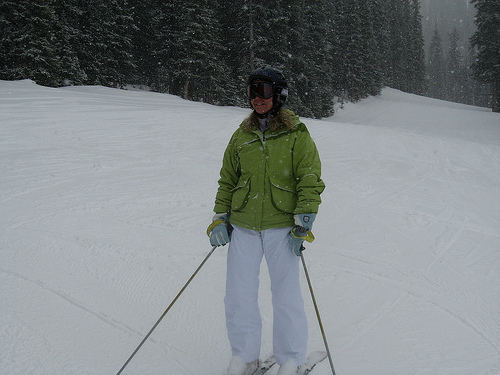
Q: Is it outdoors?
A: Yes, it is outdoors.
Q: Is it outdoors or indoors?
A: It is outdoors.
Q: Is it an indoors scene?
A: No, it is outdoors.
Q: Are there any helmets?
A: Yes, there is a helmet.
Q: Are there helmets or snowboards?
A: Yes, there is a helmet.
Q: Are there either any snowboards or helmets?
A: Yes, there is a helmet.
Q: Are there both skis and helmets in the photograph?
A: Yes, there are both a helmet and skis.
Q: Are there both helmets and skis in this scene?
A: Yes, there are both a helmet and skis.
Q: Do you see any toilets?
A: No, there are no toilets.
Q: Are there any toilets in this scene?
A: No, there are no toilets.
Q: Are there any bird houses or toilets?
A: No, there are no toilets or bird houses.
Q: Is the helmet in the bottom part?
A: No, the helmet is in the top of the image.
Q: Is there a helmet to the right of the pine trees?
A: Yes, there is a helmet to the right of the pine trees.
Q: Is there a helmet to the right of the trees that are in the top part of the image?
A: Yes, there is a helmet to the right of the pine trees.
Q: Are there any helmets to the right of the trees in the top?
A: Yes, there is a helmet to the right of the pine trees.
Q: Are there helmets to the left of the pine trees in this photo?
A: No, the helmet is to the right of the pine trees.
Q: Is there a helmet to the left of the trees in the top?
A: No, the helmet is to the right of the pine trees.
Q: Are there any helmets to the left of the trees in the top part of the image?
A: No, the helmet is to the right of the pine trees.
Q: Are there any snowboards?
A: No, there are no snowboards.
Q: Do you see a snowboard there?
A: No, there are no snowboards.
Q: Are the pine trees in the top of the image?
A: Yes, the pine trees are in the top of the image.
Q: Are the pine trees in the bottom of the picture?
A: No, the pine trees are in the top of the image.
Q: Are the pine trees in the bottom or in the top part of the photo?
A: The pine trees are in the top of the image.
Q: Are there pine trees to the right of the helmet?
A: No, the pine trees are to the left of the helmet.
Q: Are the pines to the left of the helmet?
A: Yes, the pines are to the left of the helmet.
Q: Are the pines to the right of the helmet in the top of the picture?
A: No, the pines are to the left of the helmet.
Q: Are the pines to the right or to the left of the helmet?
A: The pines are to the left of the helmet.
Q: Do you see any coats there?
A: Yes, there is a coat.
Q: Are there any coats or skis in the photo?
A: Yes, there is a coat.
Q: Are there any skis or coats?
A: Yes, there is a coat.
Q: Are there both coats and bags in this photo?
A: No, there is a coat but no bags.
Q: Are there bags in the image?
A: No, there are no bags.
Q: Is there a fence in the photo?
A: No, there are no fences.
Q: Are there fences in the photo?
A: No, there are no fences.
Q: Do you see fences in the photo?
A: No, there are no fences.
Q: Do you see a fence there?
A: No, there are no fences.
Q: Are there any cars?
A: No, there are no cars.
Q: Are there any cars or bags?
A: No, there are no cars or bags.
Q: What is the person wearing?
A: The person is wearing trousers.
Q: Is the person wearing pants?
A: Yes, the person is wearing pants.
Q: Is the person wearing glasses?
A: No, the person is wearing pants.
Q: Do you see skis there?
A: Yes, there are skis.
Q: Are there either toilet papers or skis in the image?
A: Yes, there are skis.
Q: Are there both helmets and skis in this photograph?
A: Yes, there are both skis and a helmet.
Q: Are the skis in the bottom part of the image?
A: Yes, the skis are in the bottom of the image.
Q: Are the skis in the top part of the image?
A: No, the skis are in the bottom of the image.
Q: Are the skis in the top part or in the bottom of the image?
A: The skis are in the bottom of the image.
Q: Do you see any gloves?
A: Yes, there are gloves.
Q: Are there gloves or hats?
A: Yes, there are gloves.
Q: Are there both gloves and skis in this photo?
A: Yes, there are both gloves and a ski.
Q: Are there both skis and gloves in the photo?
A: Yes, there are both gloves and a ski.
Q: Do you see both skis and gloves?
A: Yes, there are both gloves and a ski.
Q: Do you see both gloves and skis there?
A: Yes, there are both gloves and a ski.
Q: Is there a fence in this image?
A: No, there are no fences.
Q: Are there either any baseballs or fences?
A: No, there are no fences or baseballs.